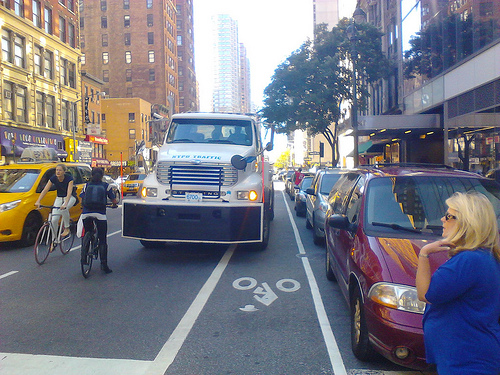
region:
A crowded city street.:
[14, 15, 486, 360]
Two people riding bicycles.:
[21, 155, 123, 282]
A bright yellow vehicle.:
[1, 140, 97, 255]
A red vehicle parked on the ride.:
[326, 150, 484, 357]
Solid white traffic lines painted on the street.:
[3, 176, 338, 371]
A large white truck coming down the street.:
[113, 98, 289, 270]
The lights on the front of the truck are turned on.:
[129, 174, 271, 215]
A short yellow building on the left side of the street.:
[95, 84, 157, 166]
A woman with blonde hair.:
[428, 186, 496, 335]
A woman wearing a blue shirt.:
[412, 175, 496, 370]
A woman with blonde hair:
[405, 170, 495, 365]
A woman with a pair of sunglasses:
[400, 180, 495, 370]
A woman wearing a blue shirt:
[410, 185, 495, 370]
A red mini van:
[315, 160, 495, 365]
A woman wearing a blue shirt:
[25, 155, 75, 260]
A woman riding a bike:
[25, 155, 80, 260]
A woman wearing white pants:
[25, 155, 75, 265]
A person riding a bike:
[65, 162, 120, 272]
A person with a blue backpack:
[75, 162, 120, 277]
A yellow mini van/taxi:
[0, 141, 101, 246]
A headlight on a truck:
[236, 189, 257, 200]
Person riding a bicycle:
[75, 165, 115, 276]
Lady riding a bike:
[34, 163, 76, 263]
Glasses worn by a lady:
[444, 213, 458, 219]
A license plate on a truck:
[184, 193, 203, 205]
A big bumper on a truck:
[122, 198, 262, 242]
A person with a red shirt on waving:
[290, 162, 304, 198]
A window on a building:
[32, 43, 43, 76]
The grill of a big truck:
[156, 160, 237, 200]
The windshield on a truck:
[166, 116, 253, 144]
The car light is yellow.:
[238, 189, 257, 201]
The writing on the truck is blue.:
[173, 154, 228, 159]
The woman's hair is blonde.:
[436, 183, 496, 251]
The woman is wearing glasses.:
[441, 192, 496, 251]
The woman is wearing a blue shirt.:
[418, 191, 498, 370]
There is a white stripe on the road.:
[178, 268, 208, 346]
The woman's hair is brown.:
[90, 163, 107, 180]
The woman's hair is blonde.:
[51, 165, 67, 183]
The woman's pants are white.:
[47, 198, 78, 239]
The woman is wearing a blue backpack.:
[81, 165, 108, 213]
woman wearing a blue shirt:
[423, 199, 499, 371]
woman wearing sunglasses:
[433, 197, 497, 252]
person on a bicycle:
[78, 167, 119, 276]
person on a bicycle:
[40, 152, 77, 260]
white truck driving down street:
[126, 107, 274, 254]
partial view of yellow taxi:
[0, 155, 49, 242]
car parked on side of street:
[325, 178, 420, 357]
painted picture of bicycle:
[233, 272, 303, 313]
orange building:
[98, 93, 148, 146]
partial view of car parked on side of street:
[304, 170, 331, 232]